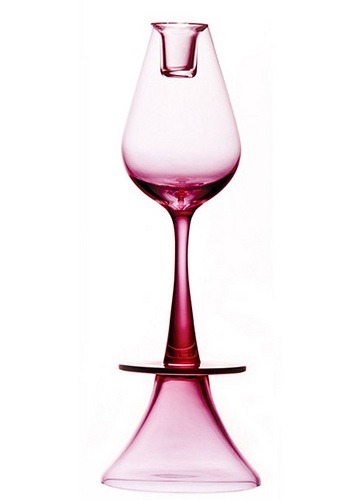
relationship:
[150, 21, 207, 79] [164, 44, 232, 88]
cube has cube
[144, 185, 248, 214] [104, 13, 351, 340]
wine in glass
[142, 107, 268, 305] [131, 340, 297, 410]
cup on stand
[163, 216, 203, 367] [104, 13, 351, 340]
middle on glass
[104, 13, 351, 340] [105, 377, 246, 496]
glass has base